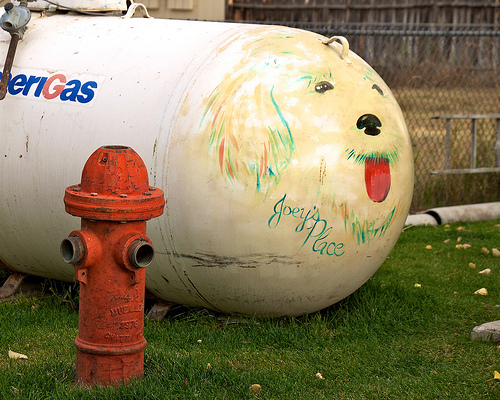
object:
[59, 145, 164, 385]
fire hydrant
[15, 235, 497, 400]
grass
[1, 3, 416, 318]
gas tank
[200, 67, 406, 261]
drawing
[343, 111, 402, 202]
paint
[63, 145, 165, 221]
cap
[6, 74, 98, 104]
logo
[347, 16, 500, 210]
fence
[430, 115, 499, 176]
ladder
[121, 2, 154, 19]
handle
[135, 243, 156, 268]
outlet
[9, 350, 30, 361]
leaf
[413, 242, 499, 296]
leaves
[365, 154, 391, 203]
tongue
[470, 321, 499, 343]
rock